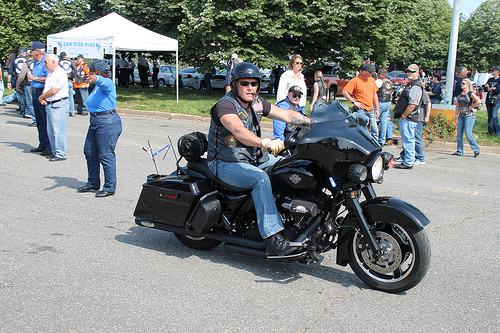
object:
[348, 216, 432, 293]
wheel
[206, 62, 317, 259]
man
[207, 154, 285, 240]
jeans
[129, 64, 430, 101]
cars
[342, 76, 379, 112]
shirt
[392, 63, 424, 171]
person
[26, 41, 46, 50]
hat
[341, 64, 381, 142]
man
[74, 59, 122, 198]
person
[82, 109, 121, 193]
blue jeans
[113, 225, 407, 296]
shadow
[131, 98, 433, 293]
motorcycle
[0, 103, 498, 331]
pavement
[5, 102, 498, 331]
road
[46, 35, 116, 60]
sign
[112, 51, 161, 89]
group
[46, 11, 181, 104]
canopy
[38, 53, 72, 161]
man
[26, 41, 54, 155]
man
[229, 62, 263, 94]
helmet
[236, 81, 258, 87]
sunglasses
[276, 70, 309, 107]
shirt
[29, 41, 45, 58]
head.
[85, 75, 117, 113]
shirt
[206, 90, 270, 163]
vest